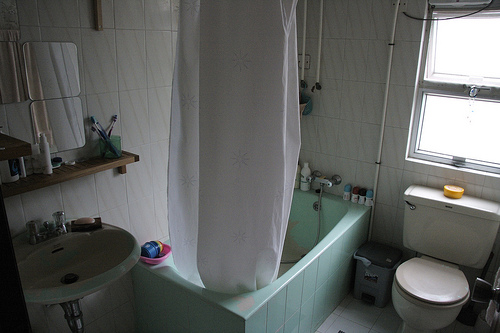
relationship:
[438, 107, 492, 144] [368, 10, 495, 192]
light shining through window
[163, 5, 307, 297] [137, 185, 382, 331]
shower curtain in tub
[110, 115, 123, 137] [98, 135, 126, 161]
toothbrush in glass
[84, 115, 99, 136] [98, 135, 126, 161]
toothbrush in glass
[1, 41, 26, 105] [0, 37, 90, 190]
squares of bathroom mirror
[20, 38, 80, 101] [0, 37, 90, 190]
squares of bathroom mirror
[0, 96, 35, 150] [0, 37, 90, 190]
squares of bathroom mirror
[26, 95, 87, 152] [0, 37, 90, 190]
squares of bathroom mirror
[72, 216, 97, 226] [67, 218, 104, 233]
soap in dish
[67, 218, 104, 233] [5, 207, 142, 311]
dish on sink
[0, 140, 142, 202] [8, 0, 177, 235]
wood shelf on wall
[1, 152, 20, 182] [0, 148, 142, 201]
toiletries on wood shelf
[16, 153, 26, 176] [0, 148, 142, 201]
toiletries on wood shelf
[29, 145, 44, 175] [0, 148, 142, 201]
toiletries on wood shelf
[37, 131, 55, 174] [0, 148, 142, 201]
toiletries on wood shelf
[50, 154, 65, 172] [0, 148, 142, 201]
toiletries on wood shelf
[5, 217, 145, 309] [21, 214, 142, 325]
sink attached to wall